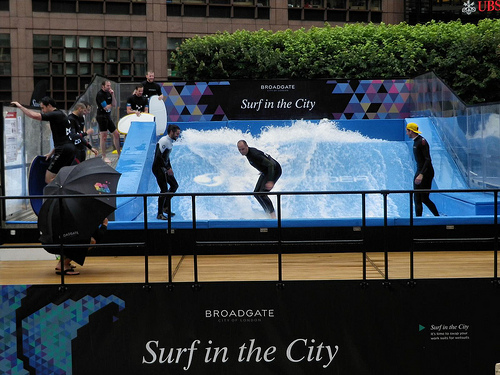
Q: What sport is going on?
A: Surfing.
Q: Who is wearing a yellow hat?
A: Person in water to right.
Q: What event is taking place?
A: Surf in the city.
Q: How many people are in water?
A: 3.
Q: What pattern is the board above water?
A: Triangles.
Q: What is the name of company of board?
A: Broadgate.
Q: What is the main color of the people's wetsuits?
A: Black.